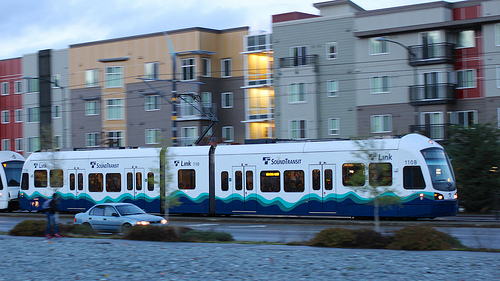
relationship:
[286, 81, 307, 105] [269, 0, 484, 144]
window part of building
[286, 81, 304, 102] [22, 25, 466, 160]
window part of building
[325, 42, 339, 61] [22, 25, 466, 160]
window part of building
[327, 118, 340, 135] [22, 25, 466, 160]
window part of building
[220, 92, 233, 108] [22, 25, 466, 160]
window part of building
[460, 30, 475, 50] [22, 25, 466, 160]
window part of building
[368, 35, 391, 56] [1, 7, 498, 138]
window part of building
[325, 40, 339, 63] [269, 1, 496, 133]
window part of building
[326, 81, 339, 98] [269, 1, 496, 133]
window part of building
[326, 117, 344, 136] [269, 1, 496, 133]
window part of building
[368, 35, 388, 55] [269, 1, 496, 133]
window part of building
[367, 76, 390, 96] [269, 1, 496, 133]
window part of building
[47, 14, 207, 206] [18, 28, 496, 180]
windows part of building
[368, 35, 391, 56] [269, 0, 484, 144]
window part of building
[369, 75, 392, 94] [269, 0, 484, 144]
window part of building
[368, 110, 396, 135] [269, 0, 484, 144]
window part of building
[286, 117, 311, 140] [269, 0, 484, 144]
window part of building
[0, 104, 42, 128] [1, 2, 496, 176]
windows part of building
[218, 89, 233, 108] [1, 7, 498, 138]
window part of building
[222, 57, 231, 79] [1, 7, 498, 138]
window part of building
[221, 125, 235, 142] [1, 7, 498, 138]
window part of building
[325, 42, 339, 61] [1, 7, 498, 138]
window part of building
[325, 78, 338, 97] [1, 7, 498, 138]
window part of building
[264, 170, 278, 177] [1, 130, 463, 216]
light shining in train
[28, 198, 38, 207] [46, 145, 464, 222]
reflection on side of train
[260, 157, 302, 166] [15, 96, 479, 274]
writing on side of train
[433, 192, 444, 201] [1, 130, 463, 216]
light of train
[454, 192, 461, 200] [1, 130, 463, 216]
light of train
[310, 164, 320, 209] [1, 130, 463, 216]
door of train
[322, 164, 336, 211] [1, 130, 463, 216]
door of train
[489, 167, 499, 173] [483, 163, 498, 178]
light of light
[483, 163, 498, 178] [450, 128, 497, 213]
light in bushes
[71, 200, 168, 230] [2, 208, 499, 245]
car on road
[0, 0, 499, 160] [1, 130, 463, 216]
building behind train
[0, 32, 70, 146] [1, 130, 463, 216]
building behind train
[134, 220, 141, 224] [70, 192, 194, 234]
light on car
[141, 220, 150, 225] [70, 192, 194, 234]
headlight on car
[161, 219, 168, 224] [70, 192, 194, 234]
headlight on car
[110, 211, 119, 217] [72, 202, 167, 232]
mirror on car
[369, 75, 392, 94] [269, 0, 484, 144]
window on building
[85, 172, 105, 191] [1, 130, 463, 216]
window on train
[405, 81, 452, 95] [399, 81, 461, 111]
railing on balcony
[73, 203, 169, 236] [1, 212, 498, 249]
car on road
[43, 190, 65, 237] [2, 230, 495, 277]
person standing on ground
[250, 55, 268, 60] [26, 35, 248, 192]
light in building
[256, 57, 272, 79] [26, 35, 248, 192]
light in building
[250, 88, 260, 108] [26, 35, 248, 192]
light in building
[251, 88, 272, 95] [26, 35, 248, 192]
light in building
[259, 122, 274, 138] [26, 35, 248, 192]
light in building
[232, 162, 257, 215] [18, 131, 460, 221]
door on train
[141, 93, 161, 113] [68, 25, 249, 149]
window in building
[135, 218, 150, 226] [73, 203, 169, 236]
headlight on car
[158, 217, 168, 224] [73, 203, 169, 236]
headlight on car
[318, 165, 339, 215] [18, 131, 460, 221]
door on train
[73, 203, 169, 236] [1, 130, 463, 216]
car on side of train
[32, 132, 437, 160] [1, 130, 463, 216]
top of train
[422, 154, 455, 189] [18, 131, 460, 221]
windsheild of train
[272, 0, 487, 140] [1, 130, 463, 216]
gray building on side of train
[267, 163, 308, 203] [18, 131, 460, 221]
window on right side of train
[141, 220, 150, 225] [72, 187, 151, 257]
headlight on car